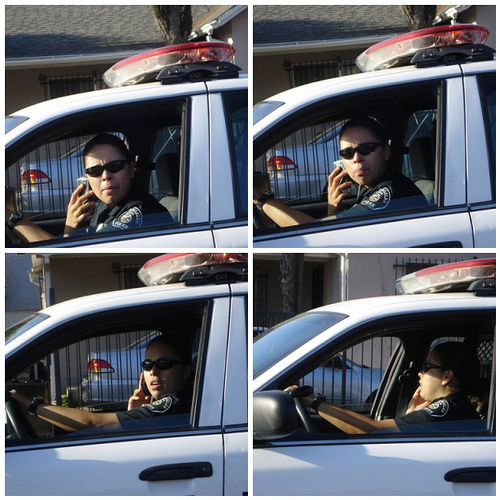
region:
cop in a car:
[99, 263, 198, 480]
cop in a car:
[339, 291, 419, 496]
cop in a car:
[345, 220, 472, 367]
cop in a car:
[279, 117, 465, 492]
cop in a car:
[305, 174, 383, 494]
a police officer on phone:
[17, 134, 169, 239]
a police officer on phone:
[266, 129, 416, 221]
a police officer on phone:
[18, 334, 198, 440]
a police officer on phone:
[302, 338, 476, 429]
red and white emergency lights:
[95, 41, 233, 79]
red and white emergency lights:
[356, 20, 483, 69]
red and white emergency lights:
[130, 252, 242, 282]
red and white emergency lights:
[390, 255, 490, 295]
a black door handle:
[135, 457, 213, 483]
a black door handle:
[445, 467, 498, 485]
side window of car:
[13, 101, 214, 228]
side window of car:
[20, 311, 201, 437]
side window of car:
[281, 327, 490, 444]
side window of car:
[268, 90, 442, 225]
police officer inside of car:
[91, 337, 183, 428]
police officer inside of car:
[353, 342, 476, 438]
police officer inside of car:
[273, 124, 430, 219]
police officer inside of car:
[46, 147, 158, 225]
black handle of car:
[139, 452, 208, 488]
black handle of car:
[431, 455, 493, 482]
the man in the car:
[62, 133, 173, 225]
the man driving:
[63, 141, 158, 226]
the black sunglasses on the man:
[78, 154, 128, 179]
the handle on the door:
[136, 456, 216, 482]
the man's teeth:
[150, 382, 159, 384]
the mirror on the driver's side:
[256, 386, 295, 440]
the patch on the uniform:
[111, 207, 138, 229]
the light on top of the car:
[110, 32, 235, 79]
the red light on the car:
[100, 35, 231, 56]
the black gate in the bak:
[61, 340, 133, 396]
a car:
[125, 179, 494, 443]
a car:
[191, 296, 412, 483]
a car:
[198, 258, 349, 440]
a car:
[241, 225, 467, 490]